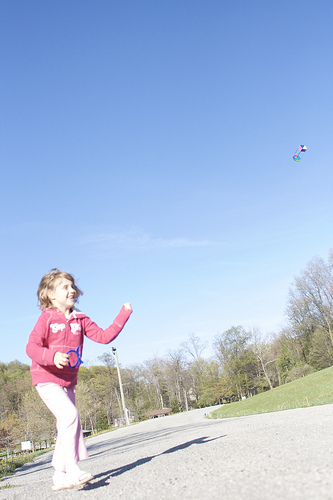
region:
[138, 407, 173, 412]
the roof of a home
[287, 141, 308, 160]
a multicolored kite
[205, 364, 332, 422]
a section of green grass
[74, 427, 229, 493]
a shadow of a girl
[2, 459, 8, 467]
a yellow flower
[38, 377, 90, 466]
a girl's pink pants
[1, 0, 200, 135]
part of a blue sky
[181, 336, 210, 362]
a tree with no leaves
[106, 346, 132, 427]
a tall gray lamp pole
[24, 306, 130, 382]
a girl's pink jacket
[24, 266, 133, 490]
a young girl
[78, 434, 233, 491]
the shadow of a little girl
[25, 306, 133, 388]
a pink jacket with white letters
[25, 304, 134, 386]
a pink jacket with a zipper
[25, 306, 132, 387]
a pink jacket with a hood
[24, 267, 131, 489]
a girl on a road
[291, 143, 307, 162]
a kite in the sky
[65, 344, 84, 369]
a blue handle to a kite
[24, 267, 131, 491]
a blonde girl flying a kite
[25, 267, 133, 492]
a little girl is smiling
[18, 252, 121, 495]
little girl running on path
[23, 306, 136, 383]
little girl's pink jacket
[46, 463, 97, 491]
white shoes of little girl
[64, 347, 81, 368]
blue handle of kite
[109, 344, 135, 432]
light pole in background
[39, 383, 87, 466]
long pants of little girl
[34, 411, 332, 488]
path girl is running on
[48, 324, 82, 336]
lettering on girl's jacket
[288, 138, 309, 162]
kite flying in the air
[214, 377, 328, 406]
grassy area beside sidewalk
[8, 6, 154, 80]
the clear blue sky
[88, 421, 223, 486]
the shadow on the ground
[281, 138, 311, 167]
the kite in the sky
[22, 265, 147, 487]
the girl holding the kite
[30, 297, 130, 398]
the girl wearing the pink hoodie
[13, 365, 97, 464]
the girl wearing the pink pants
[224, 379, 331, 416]
the grass is trimmed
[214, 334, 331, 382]
the trees with leaves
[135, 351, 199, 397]
the trees without leaves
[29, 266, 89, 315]
the girl is happy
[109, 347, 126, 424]
a tall gray pole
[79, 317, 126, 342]
the arm of a girl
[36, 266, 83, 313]
a girl's brown hair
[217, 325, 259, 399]
a tall green tree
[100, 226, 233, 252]
a small white cloud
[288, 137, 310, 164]
a colorful kite